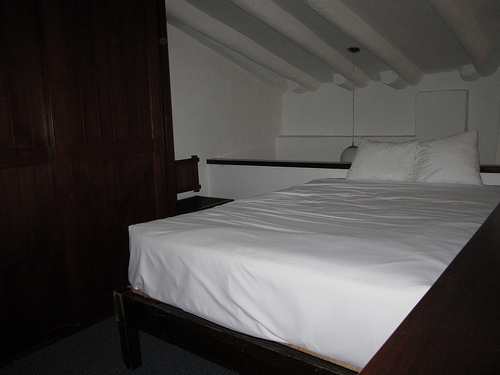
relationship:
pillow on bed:
[342, 137, 415, 181] [116, 126, 499, 370]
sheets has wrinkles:
[127, 179, 498, 369] [220, 202, 342, 228]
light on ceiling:
[168, 0, 327, 99] [164, 2, 498, 85]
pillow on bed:
[415, 138, 482, 186] [116, 126, 499, 370]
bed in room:
[116, 126, 499, 370] [3, 4, 494, 374]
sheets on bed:
[127, 179, 498, 369] [116, 126, 499, 370]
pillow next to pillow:
[342, 137, 415, 181] [415, 138, 482, 186]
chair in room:
[171, 154, 234, 209] [3, 4, 494, 374]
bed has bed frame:
[116, 126, 499, 370] [114, 291, 330, 367]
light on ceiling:
[300, 1, 422, 85] [164, 2, 498, 85]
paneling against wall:
[5, 3, 165, 373] [269, 84, 499, 171]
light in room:
[332, 144, 365, 165] [3, 4, 494, 374]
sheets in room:
[127, 179, 498, 369] [3, 4, 494, 374]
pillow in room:
[342, 137, 415, 181] [3, 4, 494, 374]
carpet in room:
[5, 297, 234, 372] [3, 4, 494, 374]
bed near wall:
[116, 126, 499, 370] [269, 84, 499, 171]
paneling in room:
[5, 3, 165, 373] [3, 4, 494, 374]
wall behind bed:
[269, 84, 499, 171] [116, 126, 499, 370]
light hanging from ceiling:
[332, 144, 365, 165] [164, 2, 498, 85]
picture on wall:
[416, 90, 472, 141] [269, 84, 499, 171]